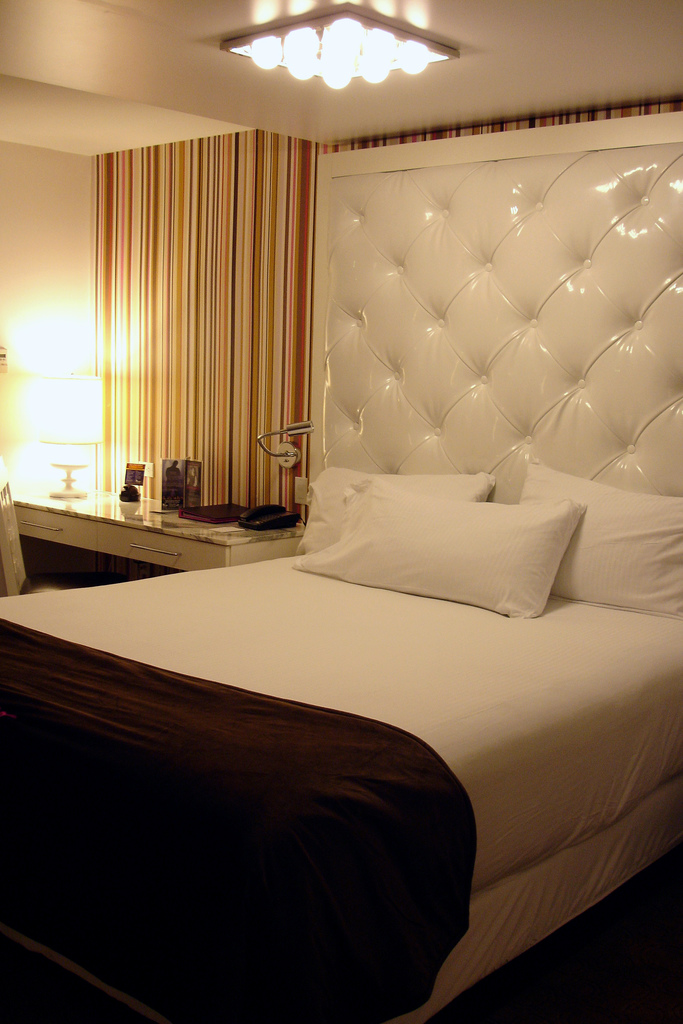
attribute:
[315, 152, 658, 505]
board — back 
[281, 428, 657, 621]
pillows — white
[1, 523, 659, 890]
sheets — white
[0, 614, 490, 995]
comforter — brown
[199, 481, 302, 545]
phone — black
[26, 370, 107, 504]
table lamp — white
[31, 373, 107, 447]
shade — white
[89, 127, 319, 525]
curtain — multi-colored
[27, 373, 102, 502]
lamp — on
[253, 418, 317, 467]
lamp — silver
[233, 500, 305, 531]
telephone — black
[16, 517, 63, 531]
handle — silver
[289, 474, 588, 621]
pillow — white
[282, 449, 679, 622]
pillows — white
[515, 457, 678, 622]
pillow — white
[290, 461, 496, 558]
pillow — white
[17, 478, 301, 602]
desk — white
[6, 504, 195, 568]
drawer handles — silver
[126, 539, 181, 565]
handle — silver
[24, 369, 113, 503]
lamp — on, white